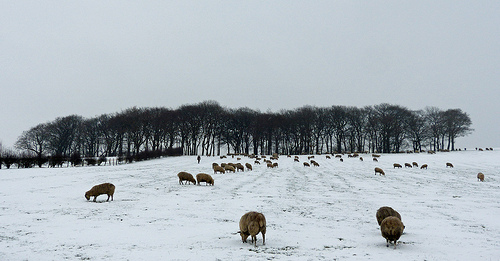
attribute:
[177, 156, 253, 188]
animals — looking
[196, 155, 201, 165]
person — here, standing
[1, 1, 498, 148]
sky — gray, white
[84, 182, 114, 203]
animal — furry, brown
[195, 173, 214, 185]
sheep — wooly, grazing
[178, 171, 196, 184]
sheep — grazing, fluffy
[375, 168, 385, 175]
sheep — here, grazing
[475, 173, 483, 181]
sheep — grazing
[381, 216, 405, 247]
sheep — fat, grazing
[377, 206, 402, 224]
sheep — brown, grey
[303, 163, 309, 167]
sheep — grey, brown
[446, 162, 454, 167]
sheep — grey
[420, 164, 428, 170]
sheep — grazing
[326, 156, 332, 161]
sheep — grazing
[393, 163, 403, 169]
sheep — grazing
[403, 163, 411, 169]
sheep — grazing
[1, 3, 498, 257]
winter — here